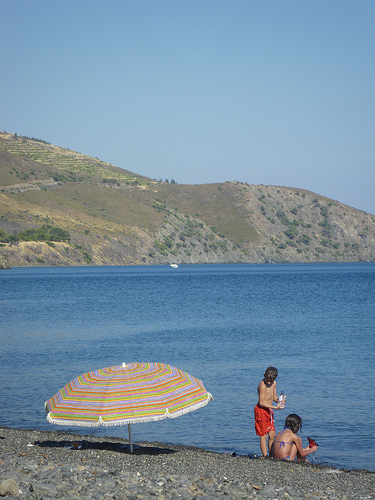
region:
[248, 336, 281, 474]
a boy standing on a beach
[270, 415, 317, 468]
a girl sitting on the ground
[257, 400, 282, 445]
a boy wearing red shorts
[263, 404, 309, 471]
a girl wearing a bathing suit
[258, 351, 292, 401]
a boy looking down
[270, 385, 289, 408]
a boy holding a plastic water bottle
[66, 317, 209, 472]
a umbrella stuck into the ground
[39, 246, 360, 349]
a large body of water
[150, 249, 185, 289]
a boat floating in the water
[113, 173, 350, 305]
a hillside next to the water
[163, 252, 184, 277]
A boat in the ocean.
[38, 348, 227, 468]
An umbrella on the beach.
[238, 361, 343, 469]
A boy and a girl playing on the beach.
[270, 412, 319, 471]
A girl playing in the sand.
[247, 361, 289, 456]
A boy holding a water bottle.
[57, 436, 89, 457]
A water bottle in the sand.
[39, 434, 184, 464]
The shade from an umbrella.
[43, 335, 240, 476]
The ocean.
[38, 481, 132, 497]
Rocks in the sand.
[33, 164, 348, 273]
Mountains next to the ocean.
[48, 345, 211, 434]
umbrella on the beach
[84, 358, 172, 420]
multi colored umbrella on beach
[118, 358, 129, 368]
white tip to umbrella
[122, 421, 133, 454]
silver pole for umbrella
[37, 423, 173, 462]
shadow of umbrella on beach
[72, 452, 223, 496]
beach covered in rocks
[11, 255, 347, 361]
large blue body of water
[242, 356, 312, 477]
two kids playing on beach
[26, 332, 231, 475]
The umbrella is colorful.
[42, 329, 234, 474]
The umbrella is open.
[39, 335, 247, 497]
The umbrella is stuck in the ground.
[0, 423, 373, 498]
The ground is rocky.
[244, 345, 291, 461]
The boy is standing near the water.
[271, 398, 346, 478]
The girl is sitting near the water.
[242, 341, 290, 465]
The boy is wearing swimming trunks.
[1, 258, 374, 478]
The water is calm.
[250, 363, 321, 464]
a boy and a girl in their swimwear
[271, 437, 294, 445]
a strap of the swimwear of the girl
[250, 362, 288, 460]
a boy holding a bottle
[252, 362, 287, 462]
a boy wearing shorts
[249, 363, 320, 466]
boy and a girl next to the body of water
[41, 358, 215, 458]
a beach umbrella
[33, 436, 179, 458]
a shadow of the beach umbrella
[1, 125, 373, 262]
a mountain line in the background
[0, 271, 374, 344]
a body of water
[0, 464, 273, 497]
pebbles on the ground